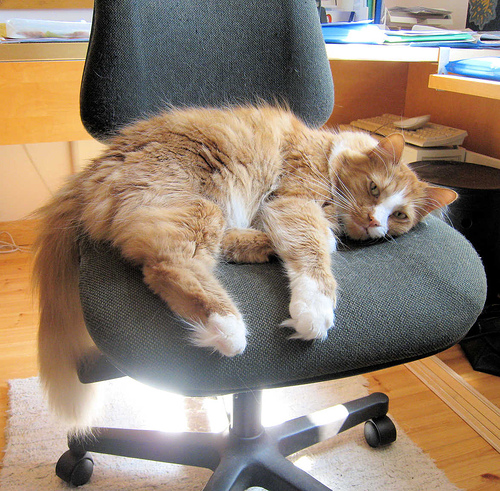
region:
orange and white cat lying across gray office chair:
[72, 6, 485, 356]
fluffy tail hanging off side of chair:
[25, 185, 105, 415]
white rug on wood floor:
[0, 245, 496, 485]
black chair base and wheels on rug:
[45, 375, 395, 485]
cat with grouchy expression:
[345, 151, 415, 246]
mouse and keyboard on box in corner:
[342, 92, 464, 163]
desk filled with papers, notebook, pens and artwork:
[320, 0, 495, 80]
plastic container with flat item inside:
[0, 1, 90, 41]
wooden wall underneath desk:
[1, 60, 492, 245]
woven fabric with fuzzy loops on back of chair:
[80, 2, 332, 137]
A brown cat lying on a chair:
[35, 108, 457, 430]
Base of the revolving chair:
[55, 390, 397, 487]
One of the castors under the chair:
[364, 418, 398, 447]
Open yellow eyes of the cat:
[368, 178, 408, 221]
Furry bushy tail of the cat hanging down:
[32, 206, 94, 443]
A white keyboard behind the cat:
[350, 113, 467, 145]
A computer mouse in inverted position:
[393, 112, 429, 127]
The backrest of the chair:
[78, 0, 332, 144]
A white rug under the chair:
[1, 376, 461, 489]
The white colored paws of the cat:
[205, 302, 334, 357]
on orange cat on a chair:
[36, 48, 456, 386]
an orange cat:
[32, 107, 455, 434]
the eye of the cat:
[368, 179, 380, 195]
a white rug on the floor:
[9, 377, 404, 489]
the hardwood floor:
[1, 255, 33, 362]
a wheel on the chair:
[363, 420, 395, 445]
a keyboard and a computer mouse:
[358, 111, 460, 151]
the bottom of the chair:
[50, 385, 399, 489]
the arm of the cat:
[273, 205, 340, 337]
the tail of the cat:
[36, 210, 90, 424]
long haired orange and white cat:
[29, 101, 458, 421]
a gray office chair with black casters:
[55, 3, 472, 483]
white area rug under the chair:
[5, 365, 457, 489]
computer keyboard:
[357, 109, 468, 153]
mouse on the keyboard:
[395, 110, 432, 130]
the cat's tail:
[28, 203, 98, 438]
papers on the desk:
[318, 8, 498, 49]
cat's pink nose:
[365, 210, 381, 226]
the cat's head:
[334, 135, 456, 243]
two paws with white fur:
[197, 283, 333, 353]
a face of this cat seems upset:
[330, 130, 435, 240]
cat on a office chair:
[35, 16, 497, 306]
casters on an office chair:
[289, 380, 399, 460]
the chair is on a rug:
[8, 368, 403, 488]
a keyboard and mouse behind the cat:
[348, 100, 462, 169]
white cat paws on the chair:
[271, 267, 356, 349]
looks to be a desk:
[338, 5, 498, 149]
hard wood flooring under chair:
[408, 383, 478, 458]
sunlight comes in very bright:
[93, 374, 200, 463]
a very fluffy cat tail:
[28, 170, 90, 490]